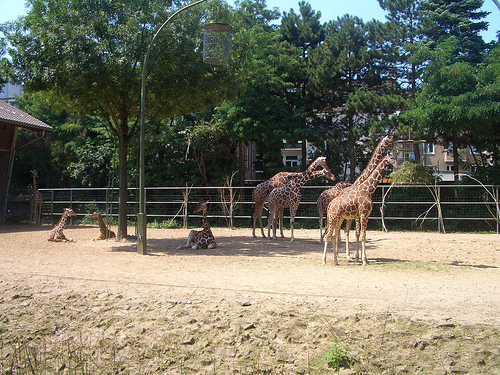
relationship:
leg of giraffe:
[61, 228, 78, 240] [52, 202, 93, 243]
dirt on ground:
[258, 269, 271, 278] [196, 255, 282, 321]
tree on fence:
[93, 7, 181, 236] [137, 162, 252, 229]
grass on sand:
[148, 216, 190, 223] [134, 274, 220, 289]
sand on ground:
[134, 274, 220, 289] [196, 255, 282, 321]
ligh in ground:
[332, 5, 345, 12] [196, 255, 282, 321]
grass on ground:
[148, 216, 190, 223] [196, 255, 282, 321]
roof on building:
[8, 108, 51, 125] [411, 122, 461, 166]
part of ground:
[169, 262, 248, 299] [196, 255, 282, 321]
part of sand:
[169, 262, 248, 299] [134, 274, 220, 289]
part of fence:
[213, 170, 243, 195] [137, 162, 252, 229]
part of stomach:
[350, 205, 368, 228] [330, 178, 368, 229]